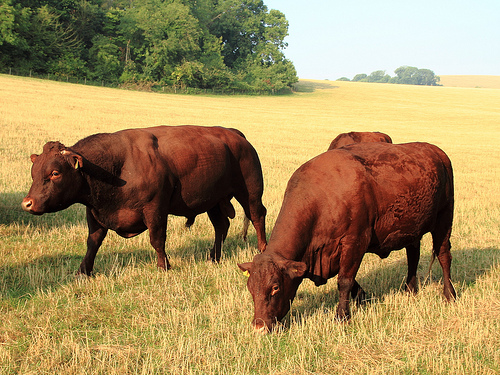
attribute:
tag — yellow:
[74, 158, 78, 170]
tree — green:
[240, 40, 300, 95]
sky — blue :
[259, 0, 498, 85]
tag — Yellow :
[242, 271, 253, 278]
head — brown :
[10, 137, 100, 222]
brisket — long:
[304, 244, 341, 276]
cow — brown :
[237, 141, 455, 331]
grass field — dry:
[0, 66, 498, 373]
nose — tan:
[17, 193, 40, 213]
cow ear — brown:
[67, 153, 82, 170]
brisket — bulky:
[95, 203, 145, 241]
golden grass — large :
[2, 79, 499, 374]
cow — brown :
[20, 122, 267, 275]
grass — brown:
[324, 79, 499, 147]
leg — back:
[403, 239, 420, 292]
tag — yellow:
[241, 267, 250, 277]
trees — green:
[1, 1, 302, 101]